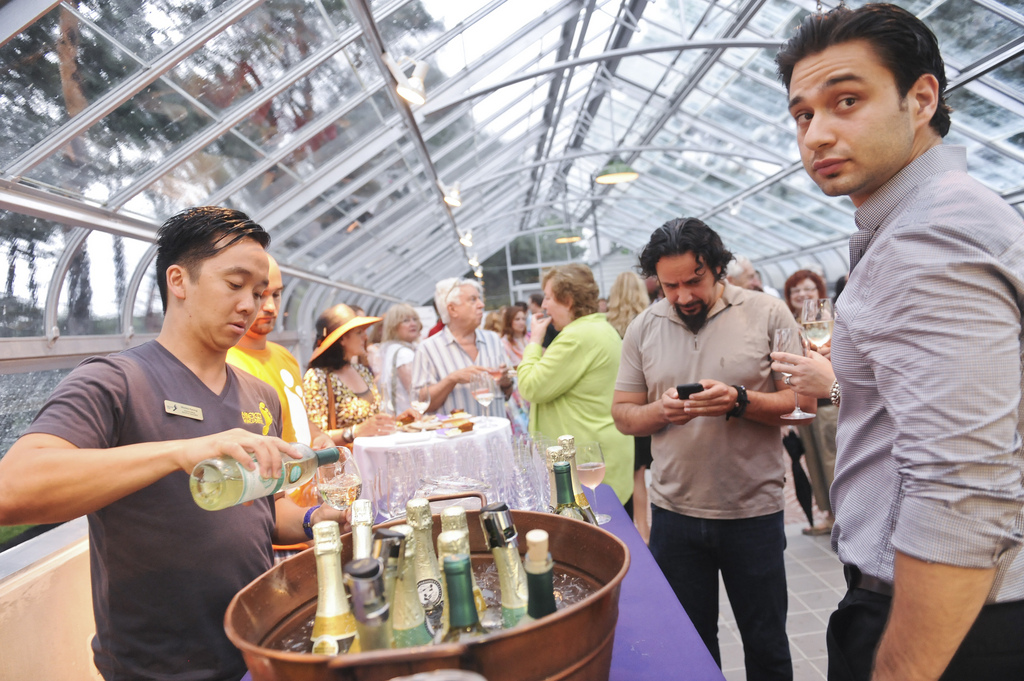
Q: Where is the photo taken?
A: In a glass archway.